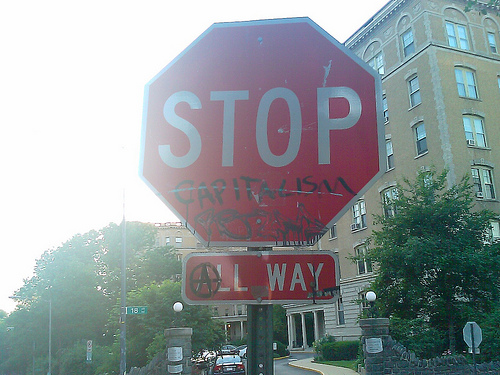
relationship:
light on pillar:
[172, 301, 182, 312] [360, 318, 392, 373]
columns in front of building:
[284, 306, 326, 353] [281, 0, 498, 352]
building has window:
[281, 0, 498, 352] [453, 67, 480, 99]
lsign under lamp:
[364, 336, 384, 354] [364, 286, 378, 311]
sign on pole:
[182, 250, 340, 305] [233, 240, 278, 374]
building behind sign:
[252, 1, 498, 336] [182, 250, 340, 305]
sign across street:
[140, 29, 410, 269] [208, 347, 310, 371]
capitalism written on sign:
[159, 166, 353, 202] [135, 16, 389, 242]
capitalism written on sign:
[174, 176, 356, 204] [132, 9, 380, 306]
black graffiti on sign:
[160, 170, 354, 210] [135, 16, 389, 242]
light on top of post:
[173, 301, 184, 312] [164, 324, 194, 374]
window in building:
[455, 66, 485, 103] [281, 0, 498, 352]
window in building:
[461, 109, 489, 154] [281, 0, 498, 352]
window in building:
[404, 65, 424, 111] [281, 0, 498, 352]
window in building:
[409, 120, 430, 161] [281, 0, 498, 352]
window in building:
[466, 162, 497, 203] [281, 0, 498, 352]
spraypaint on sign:
[173, 170, 361, 237] [125, 5, 415, 270]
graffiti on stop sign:
[168, 174, 346, 209] [153, 22, 388, 273]